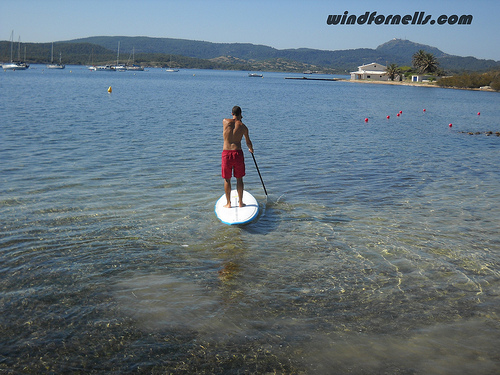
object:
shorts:
[221, 149, 246, 179]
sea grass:
[12, 201, 495, 368]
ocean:
[0, 65, 499, 374]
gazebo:
[411, 73, 422, 82]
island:
[333, 61, 500, 93]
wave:
[407, 240, 492, 310]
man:
[221, 105, 254, 208]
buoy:
[107, 86, 112, 93]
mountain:
[0, 35, 500, 74]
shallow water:
[111, 271, 500, 373]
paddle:
[251, 152, 268, 196]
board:
[214, 189, 258, 226]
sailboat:
[44, 43, 65, 70]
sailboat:
[165, 55, 179, 73]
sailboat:
[109, 39, 125, 71]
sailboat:
[88, 46, 99, 71]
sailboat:
[0, 30, 30, 71]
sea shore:
[336, 73, 498, 101]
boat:
[248, 73, 264, 77]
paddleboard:
[213, 106, 268, 226]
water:
[0, 62, 499, 374]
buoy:
[365, 117, 369, 122]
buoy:
[387, 115, 390, 119]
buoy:
[449, 123, 453, 127]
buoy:
[477, 112, 481, 115]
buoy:
[423, 109, 426, 112]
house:
[350, 62, 390, 81]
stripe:
[217, 211, 244, 227]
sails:
[49, 32, 55, 63]